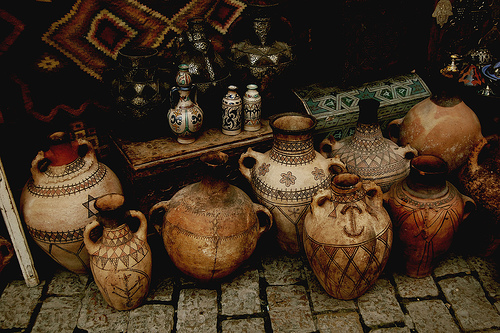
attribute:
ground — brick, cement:
[8, 269, 491, 332]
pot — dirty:
[311, 184, 404, 296]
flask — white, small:
[164, 63, 214, 141]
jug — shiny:
[236, 101, 328, 273]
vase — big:
[395, 150, 462, 296]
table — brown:
[107, 78, 372, 165]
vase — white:
[241, 121, 348, 254]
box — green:
[293, 80, 424, 118]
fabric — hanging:
[28, 18, 250, 102]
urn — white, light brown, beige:
[165, 64, 211, 160]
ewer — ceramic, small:
[221, 82, 244, 136]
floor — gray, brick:
[46, 272, 478, 331]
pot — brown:
[101, 34, 178, 145]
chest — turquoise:
[297, 77, 451, 122]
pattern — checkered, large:
[13, 3, 279, 70]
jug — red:
[27, 117, 116, 283]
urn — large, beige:
[18, 117, 130, 287]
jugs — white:
[213, 87, 272, 141]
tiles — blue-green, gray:
[170, 282, 297, 332]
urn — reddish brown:
[400, 150, 467, 288]